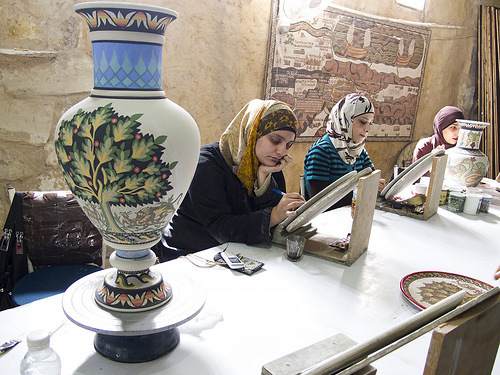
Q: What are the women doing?
A: Painting.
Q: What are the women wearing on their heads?
A: Scarves.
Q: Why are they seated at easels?
A: To paint.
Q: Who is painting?
A: The women.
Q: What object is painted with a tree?
A: A vase.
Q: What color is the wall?
A: Tan.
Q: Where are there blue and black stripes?
A: On the center womans shirt.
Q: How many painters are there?
A: Three.